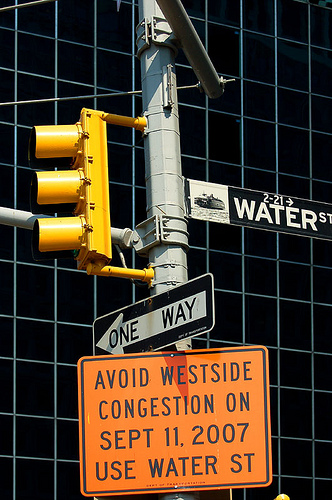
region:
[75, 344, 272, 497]
a traffic sign to avoid the Westside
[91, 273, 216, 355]
a black and white One Way sign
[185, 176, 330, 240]
black and white water street sign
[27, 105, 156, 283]
a yellow three light traffic sign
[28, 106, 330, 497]
four signs on a metal pole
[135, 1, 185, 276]
a silver metal pool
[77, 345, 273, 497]
an orange and blue street sign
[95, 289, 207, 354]
a white arrow on the black sign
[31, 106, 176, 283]
a yellow traffic light sign on a metal pole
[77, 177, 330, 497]
three street and traffic signs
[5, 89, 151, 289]
the traffic light is yellow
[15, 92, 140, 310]
the traffic light is yellow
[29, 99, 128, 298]
the traffic light is yellow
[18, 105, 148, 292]
the traffic light is yellow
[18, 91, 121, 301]
the traffic light is yellow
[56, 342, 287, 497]
the sign is orange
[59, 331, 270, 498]
the sign is orange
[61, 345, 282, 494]
the sign is orange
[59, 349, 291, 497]
the sign is orange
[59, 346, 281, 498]
the sign is orange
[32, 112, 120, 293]
yellow traffic light on pole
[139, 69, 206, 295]
grey pole with signs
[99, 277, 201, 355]
black and white sign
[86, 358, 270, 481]
black and orange sign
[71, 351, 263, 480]
black border on sign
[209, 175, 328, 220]
black and white street sign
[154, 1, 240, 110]
grey pole above street sign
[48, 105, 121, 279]
yellow housing for traffic lights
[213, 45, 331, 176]
black building in background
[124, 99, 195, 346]
the pole is gray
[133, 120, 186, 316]
the pole is gray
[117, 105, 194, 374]
the pole is gray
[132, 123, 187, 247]
the pole is gray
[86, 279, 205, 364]
the sign says one way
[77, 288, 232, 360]
the sign says one way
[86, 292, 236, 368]
the sign says one way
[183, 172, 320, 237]
A street direction banner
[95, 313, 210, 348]
A street direction banner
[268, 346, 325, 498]
A tall pane wall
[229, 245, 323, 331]
A tall pane wall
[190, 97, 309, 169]
A tall pane wall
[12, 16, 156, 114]
A tall pane wall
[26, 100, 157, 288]
A yellow traffic light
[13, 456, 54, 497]
a window on a building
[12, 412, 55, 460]
a window on a building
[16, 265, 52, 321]
a window on a building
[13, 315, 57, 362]
a window on a building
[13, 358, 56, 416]
a window on a building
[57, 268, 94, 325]
a window on a building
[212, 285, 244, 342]
a window on a building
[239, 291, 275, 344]
a window on a building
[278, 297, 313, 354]
a window on a building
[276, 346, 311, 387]
a window on a building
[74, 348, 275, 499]
Orange and black sign on a pole.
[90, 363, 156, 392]
AVOID, written on an orange sign.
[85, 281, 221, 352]
Black and white "One Way" sign.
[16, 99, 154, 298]
Yellow traffic signal on a pole.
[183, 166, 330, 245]
Black and white "Water Street" sign.